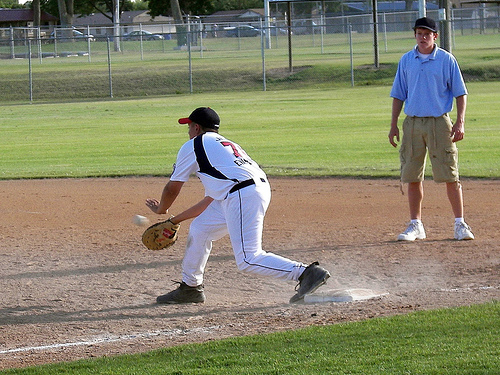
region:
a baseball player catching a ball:
[132, 104, 332, 306]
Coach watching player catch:
[387, 16, 476, 242]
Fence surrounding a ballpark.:
[2, 5, 498, 109]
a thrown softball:
[132, 212, 150, 230]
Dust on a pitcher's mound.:
[298, 282, 392, 306]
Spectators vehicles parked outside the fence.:
[46, 25, 301, 45]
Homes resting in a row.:
[0, 1, 499, 42]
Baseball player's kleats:
[152, 260, 329, 305]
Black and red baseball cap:
[176, 105, 226, 133]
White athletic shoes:
[397, 218, 475, 243]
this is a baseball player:
[132, 97, 296, 312]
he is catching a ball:
[136, 215, 185, 252]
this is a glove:
[156, 224, 178, 242]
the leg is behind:
[238, 244, 336, 286]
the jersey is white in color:
[209, 169, 266, 240]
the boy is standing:
[368, 8, 472, 245]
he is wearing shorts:
[402, 117, 444, 170]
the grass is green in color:
[301, 111, 357, 161]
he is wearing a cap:
[193, 105, 209, 120]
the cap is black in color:
[200, 110, 217, 122]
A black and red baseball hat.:
[178, 107, 223, 132]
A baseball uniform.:
[161, 131, 316, 306]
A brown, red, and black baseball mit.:
[139, 214, 182, 251]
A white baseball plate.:
[301, 279, 385, 304]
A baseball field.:
[4, 72, 493, 373]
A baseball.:
[129, 213, 148, 227]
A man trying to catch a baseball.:
[113, 107, 340, 308]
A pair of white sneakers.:
[393, 218, 471, 243]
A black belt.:
[227, 176, 267, 193]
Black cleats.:
[157, 264, 330, 315]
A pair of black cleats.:
[158, 264, 333, 307]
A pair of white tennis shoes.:
[397, 220, 473, 242]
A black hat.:
[411, 17, 438, 33]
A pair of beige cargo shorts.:
[401, 117, 457, 184]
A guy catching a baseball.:
[128, 107, 331, 316]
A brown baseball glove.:
[142, 214, 180, 251]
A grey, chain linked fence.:
[0, 12, 497, 99]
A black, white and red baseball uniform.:
[169, 134, 308, 284]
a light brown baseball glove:
[139, 219, 177, 252]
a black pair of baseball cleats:
[155, 266, 330, 304]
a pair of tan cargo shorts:
[397, 115, 457, 183]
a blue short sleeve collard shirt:
[393, 48, 464, 115]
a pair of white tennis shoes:
[398, 219, 473, 242]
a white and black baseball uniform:
[169, 137, 301, 287]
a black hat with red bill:
[176, 105, 224, 130]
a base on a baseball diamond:
[305, 270, 376, 307]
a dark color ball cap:
[414, 16, 438, 31]